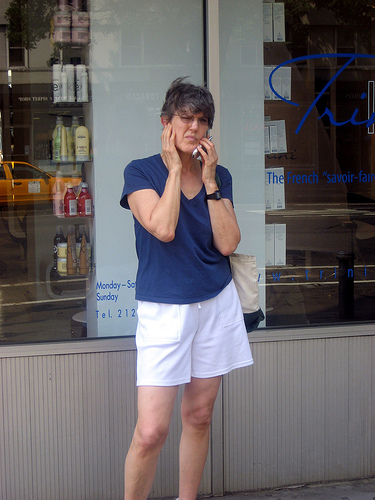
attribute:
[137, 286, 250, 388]
shorts — WHITE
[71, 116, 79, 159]
bottle — plastic, yellow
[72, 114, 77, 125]
cap — silver